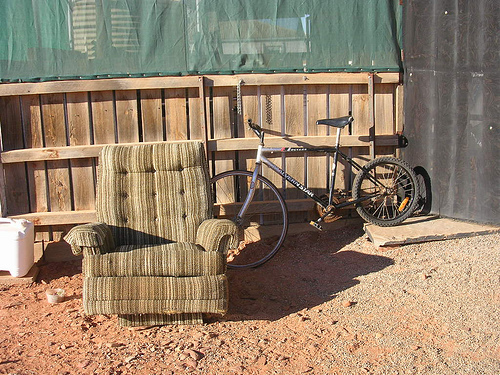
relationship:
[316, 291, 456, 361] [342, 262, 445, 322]
dirt on ground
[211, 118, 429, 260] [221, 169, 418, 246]
bicycle with wheels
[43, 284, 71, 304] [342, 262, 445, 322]
bowl on ground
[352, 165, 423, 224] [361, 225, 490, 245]
bicycle tire on concrete slab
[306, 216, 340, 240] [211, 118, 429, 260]
pedal on bicycle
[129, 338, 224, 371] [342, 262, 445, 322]
rocks on ground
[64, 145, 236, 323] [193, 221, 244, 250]
chair has arm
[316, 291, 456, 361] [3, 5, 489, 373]
dirt in yard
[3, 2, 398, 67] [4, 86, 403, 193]
screen on wall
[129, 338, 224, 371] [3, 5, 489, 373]
rocks in yard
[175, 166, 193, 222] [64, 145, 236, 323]
buttons on recliner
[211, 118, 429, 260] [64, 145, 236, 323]
bicycle beside couch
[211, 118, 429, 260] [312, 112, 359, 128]
bicycle has seat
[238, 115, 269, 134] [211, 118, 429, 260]
handlebars are of bike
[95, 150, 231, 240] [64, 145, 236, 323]
sun shining on chair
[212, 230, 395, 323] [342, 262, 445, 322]
shadow on ground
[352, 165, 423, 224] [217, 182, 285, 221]
bikewheel with spokes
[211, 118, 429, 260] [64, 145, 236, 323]
bike next to chair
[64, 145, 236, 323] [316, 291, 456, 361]
chair on dirt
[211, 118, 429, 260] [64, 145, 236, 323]
bicycle behind chair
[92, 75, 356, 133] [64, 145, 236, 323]
fence behind chair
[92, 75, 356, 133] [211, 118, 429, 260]
fence behind bicycle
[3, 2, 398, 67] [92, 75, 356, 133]
tarp attached fence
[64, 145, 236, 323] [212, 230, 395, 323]
chair has shadow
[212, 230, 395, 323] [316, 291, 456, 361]
shadow on dirt